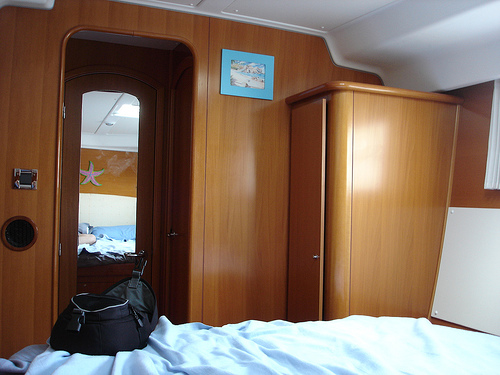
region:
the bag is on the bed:
[73, 268, 195, 344]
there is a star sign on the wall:
[79, 154, 128, 205]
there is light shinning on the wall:
[331, 136, 408, 201]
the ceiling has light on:
[104, 111, 162, 141]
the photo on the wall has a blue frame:
[216, 38, 301, 108]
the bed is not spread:
[169, 317, 385, 374]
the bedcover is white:
[189, 323, 384, 363]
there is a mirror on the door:
[83, 89, 157, 285]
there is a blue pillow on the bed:
[88, 217, 141, 242]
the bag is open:
[71, 231, 181, 349]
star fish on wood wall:
[74, 157, 110, 193]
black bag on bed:
[51, 258, 168, 362]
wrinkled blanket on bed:
[201, 321, 338, 365]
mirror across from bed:
[71, 82, 146, 272]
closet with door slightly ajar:
[273, 85, 340, 311]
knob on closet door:
[310, 245, 322, 265]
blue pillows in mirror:
[92, 219, 137, 247]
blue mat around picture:
[212, 40, 280, 101]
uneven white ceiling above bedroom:
[309, 12, 489, 68]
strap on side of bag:
[123, 255, 149, 290]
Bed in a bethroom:
[14, 5, 491, 372]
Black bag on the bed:
[41, 249, 165, 360]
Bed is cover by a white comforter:
[0, 303, 499, 373]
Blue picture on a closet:
[211, 39, 283, 109]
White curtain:
[472, 81, 499, 196]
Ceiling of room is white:
[156, 0, 491, 60]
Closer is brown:
[0, 0, 442, 362]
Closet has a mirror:
[71, 82, 157, 287]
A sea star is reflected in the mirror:
[78, 156, 112, 198]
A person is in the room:
[74, 221, 111, 257]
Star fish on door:
[81, 150, 109, 192]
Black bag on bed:
[25, 259, 177, 363]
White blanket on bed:
[194, 320, 368, 362]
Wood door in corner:
[269, 100, 378, 320]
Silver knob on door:
[302, 233, 341, 296]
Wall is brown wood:
[191, 35, 261, 272]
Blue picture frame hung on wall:
[218, 45, 318, 156]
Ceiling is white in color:
[98, 108, 118, 142]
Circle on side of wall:
[11, 204, 39, 276]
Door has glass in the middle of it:
[66, 75, 150, 285]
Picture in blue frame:
[210, 41, 282, 109]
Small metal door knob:
[307, 247, 325, 264]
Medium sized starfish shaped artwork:
[69, 153, 110, 197]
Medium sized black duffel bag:
[39, 250, 181, 367]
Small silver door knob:
[155, 218, 186, 249]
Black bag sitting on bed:
[7, 231, 190, 373]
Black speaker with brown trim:
[0, 203, 50, 265]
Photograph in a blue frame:
[207, 36, 298, 114]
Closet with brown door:
[252, 80, 470, 327]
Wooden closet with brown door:
[248, 56, 483, 327]